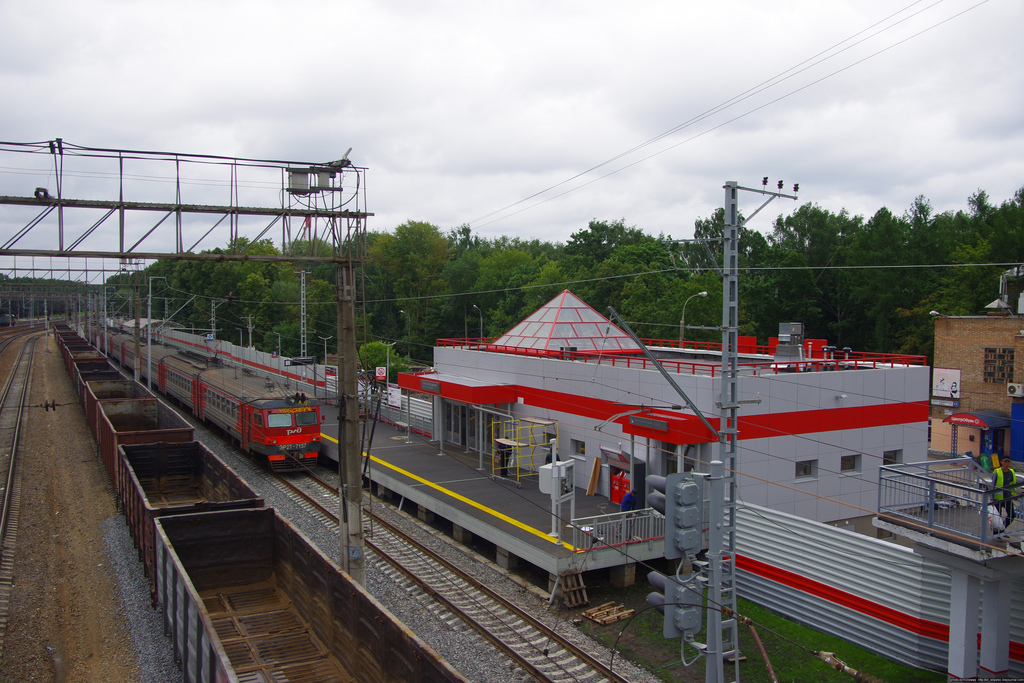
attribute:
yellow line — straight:
[311, 419, 588, 560]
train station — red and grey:
[393, 284, 931, 525]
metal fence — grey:
[717, 489, 1021, 677]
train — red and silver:
[78, 311, 323, 476]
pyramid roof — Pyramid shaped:
[482, 283, 651, 359]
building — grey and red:
[916, 290, 1021, 465]